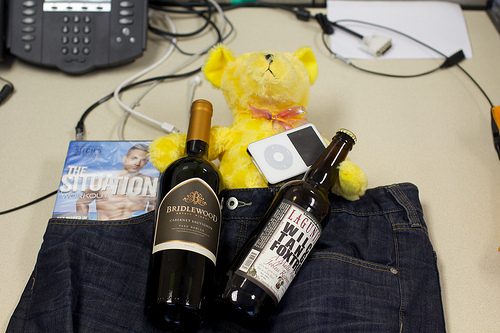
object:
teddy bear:
[144, 43, 369, 204]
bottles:
[140, 98, 227, 328]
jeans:
[6, 183, 445, 333]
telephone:
[0, 0, 150, 75]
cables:
[76, 6, 467, 134]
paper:
[326, 2, 471, 60]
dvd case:
[53, 136, 167, 224]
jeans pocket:
[41, 208, 156, 275]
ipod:
[247, 123, 328, 183]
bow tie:
[248, 104, 308, 134]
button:
[225, 197, 240, 211]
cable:
[323, 18, 392, 56]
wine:
[144, 99, 226, 328]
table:
[2, 3, 500, 332]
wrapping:
[185, 98, 213, 144]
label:
[150, 177, 224, 265]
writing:
[165, 204, 175, 214]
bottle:
[220, 126, 359, 320]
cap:
[337, 128, 360, 143]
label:
[234, 198, 322, 306]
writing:
[281, 222, 301, 237]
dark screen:
[289, 124, 326, 170]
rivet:
[390, 267, 399, 275]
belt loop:
[387, 185, 422, 228]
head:
[201, 41, 319, 115]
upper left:
[0, 1, 187, 112]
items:
[0, 45, 454, 333]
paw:
[328, 160, 369, 201]